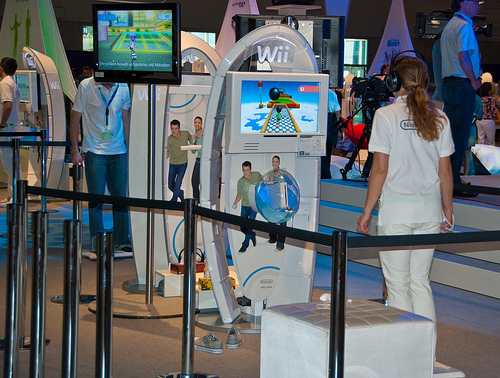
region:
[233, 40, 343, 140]
a wii game station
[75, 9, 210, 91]
a tv suspended from ceiling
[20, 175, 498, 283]
a rail or divider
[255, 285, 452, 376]
a white cube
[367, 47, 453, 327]
a woman with headphones on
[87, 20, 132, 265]
a man with a lanyard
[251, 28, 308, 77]
wii in large white lettering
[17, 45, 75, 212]
a wii console in the background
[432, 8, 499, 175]
a man to the right of the console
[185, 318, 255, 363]
a pair of shoes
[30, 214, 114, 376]
silver metal barrier poles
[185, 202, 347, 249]
black guard strapping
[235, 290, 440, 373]
large white bench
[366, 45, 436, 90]
woman in black headphones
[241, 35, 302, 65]
brand logo above television monitor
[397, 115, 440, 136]
company name on back of shirt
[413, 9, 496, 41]
man holding large television video camera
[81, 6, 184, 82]
black flat screen television monitor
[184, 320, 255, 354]
pair of grey and white tennis shoes on floor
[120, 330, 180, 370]
ground covered in brown carpet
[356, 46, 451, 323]
A woman in a white shirt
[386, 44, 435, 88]
A pair of black headphones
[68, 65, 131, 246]
A man in a white shirt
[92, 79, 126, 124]
A blue lanyard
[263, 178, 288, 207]
A white wii game console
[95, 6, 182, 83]
A black television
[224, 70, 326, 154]
A white television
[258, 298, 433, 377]
A white ottoman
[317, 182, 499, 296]
A small set of white stairs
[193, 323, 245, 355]
A pair of shoes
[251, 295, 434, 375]
White ottoman on floor.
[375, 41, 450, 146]
Pony tail on women's head.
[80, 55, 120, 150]
Identification badge on front of man.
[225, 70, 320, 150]
Wii game on monitor.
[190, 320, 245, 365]
Tan shoes on floor.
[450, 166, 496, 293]
Platform in the room.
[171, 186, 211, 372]
Silver pole threaded with black material.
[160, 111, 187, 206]
Man on the sign.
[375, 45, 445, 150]
Woman is wearing head phones.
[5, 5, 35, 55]
Wall design of people characters.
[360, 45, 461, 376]
this is a person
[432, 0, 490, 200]
this is a person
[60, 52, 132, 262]
this is a person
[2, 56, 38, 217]
this is a person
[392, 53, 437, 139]
the hair is in a pony tail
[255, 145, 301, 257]
a picture of a person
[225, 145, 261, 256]
a picture of a person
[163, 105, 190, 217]
a picture of a person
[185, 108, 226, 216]
a picture of a person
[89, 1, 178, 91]
this is a tv screen